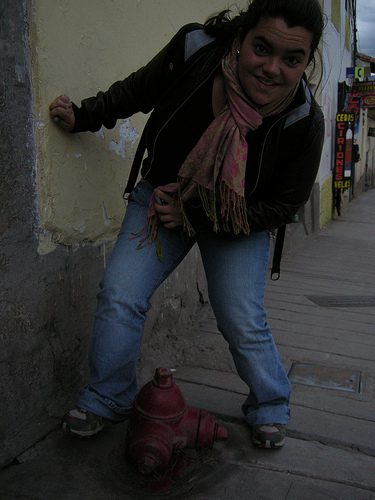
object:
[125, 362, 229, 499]
fire hydrant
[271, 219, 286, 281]
buckle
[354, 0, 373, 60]
sky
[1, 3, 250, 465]
wall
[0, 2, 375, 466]
building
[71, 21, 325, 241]
black jacket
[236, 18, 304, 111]
face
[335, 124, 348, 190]
sign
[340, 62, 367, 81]
sign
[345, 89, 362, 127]
sign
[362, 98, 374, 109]
sign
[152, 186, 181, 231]
hand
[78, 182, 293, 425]
blue jeans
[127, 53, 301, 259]
scarf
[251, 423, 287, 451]
shoe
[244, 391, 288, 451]
foot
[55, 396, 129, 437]
shoe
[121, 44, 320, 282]
backpack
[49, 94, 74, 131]
hand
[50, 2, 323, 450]
lady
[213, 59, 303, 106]
woman's neck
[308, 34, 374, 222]
background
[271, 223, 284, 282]
strap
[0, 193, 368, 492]
ground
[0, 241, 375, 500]
sidewalk